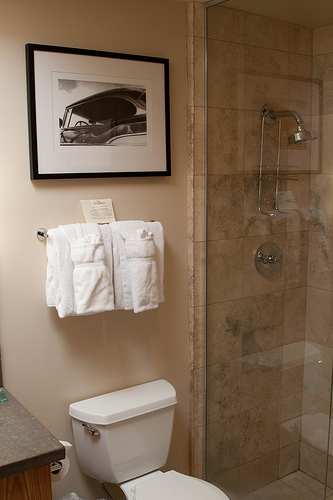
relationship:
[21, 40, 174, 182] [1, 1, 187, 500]
picture on wall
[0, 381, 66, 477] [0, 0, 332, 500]
counter in bathroom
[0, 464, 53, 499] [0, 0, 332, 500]
cabinet in bathroom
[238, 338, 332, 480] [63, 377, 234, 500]
reflection of toilet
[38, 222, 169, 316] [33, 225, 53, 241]
towels on towel rack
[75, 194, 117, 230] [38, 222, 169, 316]
note above towels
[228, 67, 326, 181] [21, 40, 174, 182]
reflection of picture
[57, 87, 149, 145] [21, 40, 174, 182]
car in picture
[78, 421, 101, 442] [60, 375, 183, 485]
flush handle on toilet tank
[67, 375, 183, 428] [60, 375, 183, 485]
cover on toilet tank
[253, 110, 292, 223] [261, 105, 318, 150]
caddy hanging from showerhead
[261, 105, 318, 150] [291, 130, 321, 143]
showerhead has rounded head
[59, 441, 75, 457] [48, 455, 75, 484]
toilet roll holder above toilet paper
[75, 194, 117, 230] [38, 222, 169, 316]
note on towels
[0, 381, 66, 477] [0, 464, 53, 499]
counter above cabinet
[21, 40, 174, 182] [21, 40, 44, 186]
picture has black frame